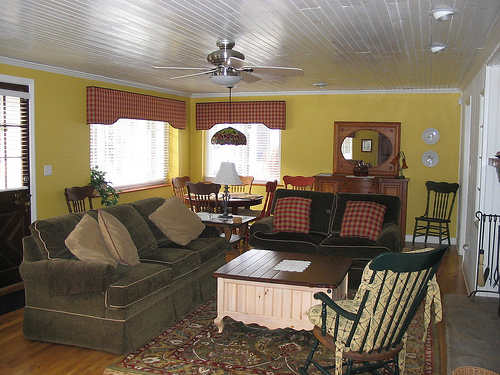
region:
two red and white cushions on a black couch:
[262, 189, 383, 240]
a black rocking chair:
[311, 251, 438, 372]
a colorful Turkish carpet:
[144, 331, 251, 371]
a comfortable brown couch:
[37, 199, 206, 345]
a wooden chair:
[418, 181, 458, 246]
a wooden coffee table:
[214, 249, 322, 331]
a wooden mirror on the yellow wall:
[325, 115, 413, 173]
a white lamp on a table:
[213, 154, 250, 224]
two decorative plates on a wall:
[415, 123, 447, 170]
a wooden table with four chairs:
[171, 172, 270, 207]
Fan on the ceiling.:
[142, 27, 307, 102]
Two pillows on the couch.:
[267, 184, 389, 246]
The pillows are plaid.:
[268, 187, 385, 248]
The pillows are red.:
[268, 187, 390, 244]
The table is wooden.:
[210, 242, 352, 346]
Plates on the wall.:
[415, 126, 442, 167]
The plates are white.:
[412, 123, 443, 168]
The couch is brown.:
[19, 190, 221, 349]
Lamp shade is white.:
[208, 157, 245, 190]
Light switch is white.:
[40, 159, 55, 180]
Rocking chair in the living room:
[298, 242, 450, 374]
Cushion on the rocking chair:
[309, 243, 435, 352]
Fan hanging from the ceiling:
[149, 35, 306, 82]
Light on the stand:
[211, 157, 241, 218]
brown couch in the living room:
[19, 195, 230, 354]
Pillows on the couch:
[65, 192, 205, 264]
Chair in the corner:
[413, 179, 458, 247]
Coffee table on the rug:
[215, 248, 352, 345]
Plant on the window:
[88, 165, 120, 207]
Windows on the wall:
[86, 83, 284, 193]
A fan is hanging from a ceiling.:
[144, 36, 316, 103]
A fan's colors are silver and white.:
[137, 33, 318, 105]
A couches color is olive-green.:
[12, 190, 248, 362]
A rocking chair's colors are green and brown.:
[285, 231, 458, 374]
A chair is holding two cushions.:
[298, 238, 450, 373]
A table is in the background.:
[162, 156, 282, 232]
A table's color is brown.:
[167, 166, 271, 226]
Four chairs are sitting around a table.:
[162, 159, 285, 235]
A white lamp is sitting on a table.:
[201, 150, 246, 227]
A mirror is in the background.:
[321, 109, 409, 181]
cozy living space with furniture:
[0, 0, 499, 372]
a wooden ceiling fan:
[150, 34, 309, 89]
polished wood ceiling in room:
[1, 0, 430, 37]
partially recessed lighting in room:
[431, 6, 453, 58]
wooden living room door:
[1, 70, 33, 292]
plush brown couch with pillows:
[17, 195, 230, 353]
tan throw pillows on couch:
[61, 207, 143, 272]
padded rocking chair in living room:
[296, 244, 445, 374]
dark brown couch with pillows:
[249, 187, 403, 259]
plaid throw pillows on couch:
[268, 192, 388, 244]